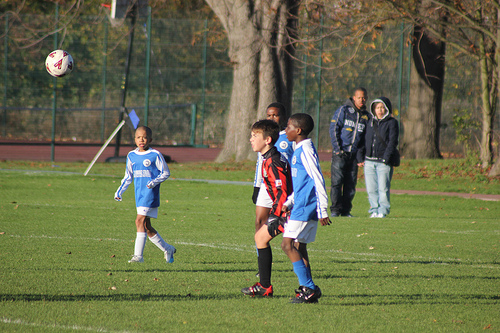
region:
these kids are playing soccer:
[42, 30, 332, 325]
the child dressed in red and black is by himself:
[136, 89, 324, 308]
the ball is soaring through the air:
[23, 29, 180, 304]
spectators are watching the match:
[208, 55, 438, 317]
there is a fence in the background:
[6, 46, 497, 173]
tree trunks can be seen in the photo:
[137, 1, 492, 172]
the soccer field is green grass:
[17, 165, 494, 325]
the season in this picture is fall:
[148, 1, 492, 200]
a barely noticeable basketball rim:
[83, 2, 160, 49]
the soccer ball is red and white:
[36, 35, 92, 82]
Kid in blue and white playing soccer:
[96, 107, 181, 304]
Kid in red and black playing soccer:
[237, 111, 321, 311]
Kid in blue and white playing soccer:
[270, 111, 338, 308]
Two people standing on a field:
[323, 73, 412, 223]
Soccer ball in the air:
[18, 31, 120, 96]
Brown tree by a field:
[208, 19, 303, 246]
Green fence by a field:
[27, 105, 63, 168]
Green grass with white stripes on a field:
[16, 172, 120, 300]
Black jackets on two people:
[315, 91, 404, 180]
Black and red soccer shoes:
[227, 268, 286, 318]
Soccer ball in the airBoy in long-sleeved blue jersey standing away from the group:
[107, 117, 188, 272]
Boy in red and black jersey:
[240, 118, 293, 305]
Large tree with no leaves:
[390, 0, 468, 167]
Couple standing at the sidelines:
[323, 79, 402, 221]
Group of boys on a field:
[236, 96, 339, 311]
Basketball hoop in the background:
[95, 0, 146, 165]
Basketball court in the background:
[0, 137, 222, 161]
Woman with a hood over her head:
[353, 96, 409, 224]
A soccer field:
[0, 174, 499, 329]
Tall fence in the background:
[2, 11, 217, 149]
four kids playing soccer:
[96, 86, 342, 311]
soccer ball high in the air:
[36, 44, 78, 81]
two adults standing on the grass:
[311, 69, 411, 219]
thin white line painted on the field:
[3, 312, 97, 331]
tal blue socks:
[287, 255, 320, 288]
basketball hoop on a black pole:
[98, 1, 173, 166]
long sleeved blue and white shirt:
[106, 143, 177, 208]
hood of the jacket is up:
[363, 89, 398, 164]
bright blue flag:
[127, 106, 142, 131]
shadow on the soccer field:
[327, 281, 499, 308]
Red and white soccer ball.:
[42, 49, 78, 79]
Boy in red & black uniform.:
[247, 119, 285, 296]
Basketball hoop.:
[95, 0, 113, 20]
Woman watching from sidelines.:
[364, 97, 396, 219]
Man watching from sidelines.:
[328, 85, 368, 218]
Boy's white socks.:
[129, 230, 179, 264]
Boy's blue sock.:
[287, 261, 317, 288]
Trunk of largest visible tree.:
[205, 0, 299, 169]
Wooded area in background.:
[1, 2, 495, 88]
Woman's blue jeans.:
[365, 160, 393, 212]